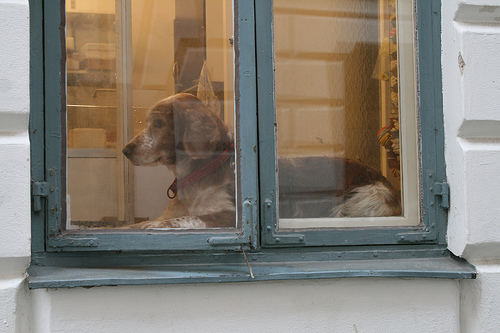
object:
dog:
[121, 91, 398, 231]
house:
[0, 2, 499, 332]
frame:
[30, 0, 446, 264]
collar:
[166, 144, 235, 199]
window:
[65, 1, 235, 227]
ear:
[181, 109, 220, 162]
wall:
[276, 7, 354, 126]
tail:
[326, 183, 397, 217]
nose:
[120, 136, 152, 168]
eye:
[153, 117, 166, 130]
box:
[71, 128, 108, 150]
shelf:
[65, 0, 118, 150]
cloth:
[197, 77, 231, 126]